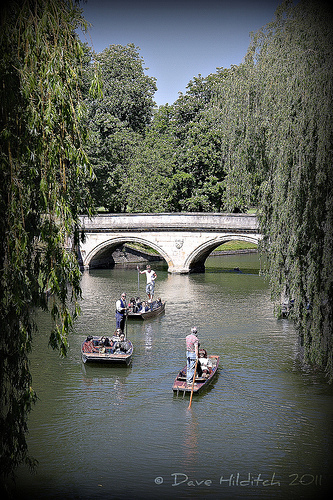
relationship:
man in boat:
[178, 322, 220, 389] [158, 348, 236, 402]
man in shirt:
[185, 326, 199, 384] [176, 330, 212, 354]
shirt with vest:
[104, 305, 140, 326] [115, 299, 127, 320]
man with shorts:
[132, 261, 207, 319] [132, 277, 161, 296]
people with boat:
[72, 290, 142, 362] [79, 339, 147, 369]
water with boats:
[74, 283, 283, 460] [68, 288, 224, 414]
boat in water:
[122, 293, 162, 319] [189, 294, 267, 336]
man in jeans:
[185, 326, 199, 384] [178, 348, 207, 389]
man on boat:
[185, 326, 199, 384] [139, 354, 219, 396]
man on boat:
[138, 265, 155, 300] [122, 294, 175, 319]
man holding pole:
[138, 265, 155, 300] [125, 258, 146, 299]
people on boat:
[85, 331, 142, 360] [71, 343, 153, 370]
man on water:
[185, 326, 199, 384] [12, 254, 333, 499]